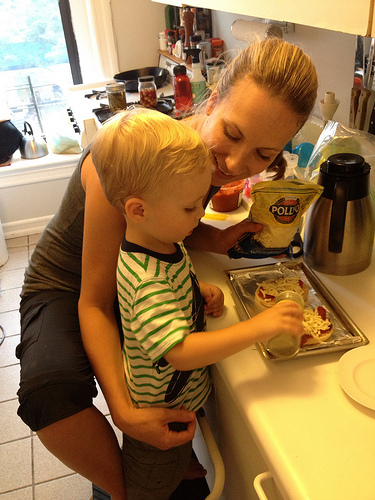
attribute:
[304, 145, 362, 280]
coffee pot — black, silver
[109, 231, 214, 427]
shirt — striped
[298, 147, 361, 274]
crafe — large, coffee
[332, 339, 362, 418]
plate — white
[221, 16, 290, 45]
rack — paper towel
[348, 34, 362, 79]
knives — kitchen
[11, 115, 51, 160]
kettle — metal, tea 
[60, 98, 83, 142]
control knobs — black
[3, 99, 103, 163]
stove — white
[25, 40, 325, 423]
woman — little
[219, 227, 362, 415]
counter — white, kitchen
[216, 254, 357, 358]
baking sheet — silver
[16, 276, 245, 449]
shorts — black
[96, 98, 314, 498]
boy — little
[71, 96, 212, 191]
hair — blonde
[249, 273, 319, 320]
pizza — uncooked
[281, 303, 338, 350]
pizza — uncooked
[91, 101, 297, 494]
boy — little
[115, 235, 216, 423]
shirt — striped, green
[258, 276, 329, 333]
pizzas — small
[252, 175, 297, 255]
bag — mozzerella, cheese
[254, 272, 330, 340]
pizzas — mini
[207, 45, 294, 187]
mom — her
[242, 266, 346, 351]
cook — son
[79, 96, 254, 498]
boy — blonde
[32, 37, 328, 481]
hair — blonde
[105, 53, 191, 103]
pan — black 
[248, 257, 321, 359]
pizzas — small 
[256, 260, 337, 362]
pizzas — uncooked , small 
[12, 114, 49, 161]
teapot — Silver 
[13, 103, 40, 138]
handle — black 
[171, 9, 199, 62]
pepper grinder — Brown , wood 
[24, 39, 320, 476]
mother — baking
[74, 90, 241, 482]
son — baking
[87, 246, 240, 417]
shirt — white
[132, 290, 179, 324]
stripes — green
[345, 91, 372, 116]
handles — wood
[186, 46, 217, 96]
spray bottle — plastic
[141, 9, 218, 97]
shelf — wood